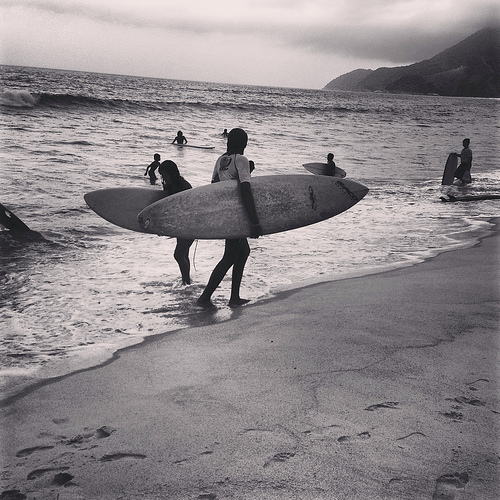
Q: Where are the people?
A: On the beach.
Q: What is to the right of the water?
A: The mountains.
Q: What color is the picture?
A: Black and white.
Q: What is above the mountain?
A: The clouds.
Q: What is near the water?
A: The sand.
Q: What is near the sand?
A: The water.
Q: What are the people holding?
A: Surfboards.